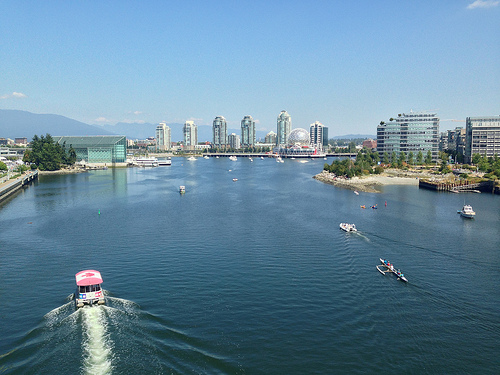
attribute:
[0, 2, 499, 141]
sky — cloudless, clear, blue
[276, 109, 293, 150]
building — distant, tall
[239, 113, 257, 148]
building — distant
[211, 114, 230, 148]
building — distant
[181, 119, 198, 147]
building — distant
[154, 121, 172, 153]
building — tan, short, distant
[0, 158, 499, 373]
water — rippled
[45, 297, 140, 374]
water — white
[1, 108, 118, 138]
mountain — distant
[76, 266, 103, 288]
roof — pink, red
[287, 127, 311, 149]
building — globular, round, central, distant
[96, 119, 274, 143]
mountain — distant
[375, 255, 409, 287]
row boat — long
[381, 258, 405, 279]
people — rowing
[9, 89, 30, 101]
cloud — white